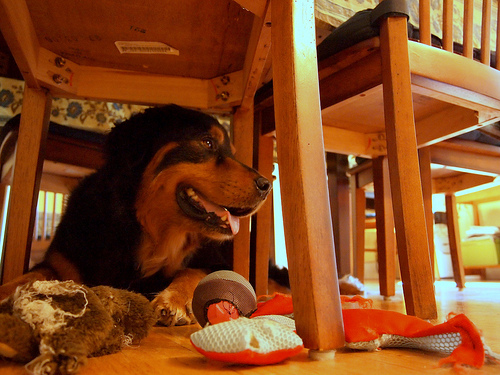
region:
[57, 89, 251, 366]
a dog is under the table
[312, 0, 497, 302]
wooden chair with cushion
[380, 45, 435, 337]
stand of the wooden chair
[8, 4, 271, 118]
wooden dining table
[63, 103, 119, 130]
white color flower designed dining table cloth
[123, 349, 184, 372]
brown color floor tiles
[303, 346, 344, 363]
rubber bush under the stand of the table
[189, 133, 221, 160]
eye of the dog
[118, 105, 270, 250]
head of the dog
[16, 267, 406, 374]
many things under the table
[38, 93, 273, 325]
a brown and black dog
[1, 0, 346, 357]
a dog sitting under a chair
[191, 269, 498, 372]
the toys of the dog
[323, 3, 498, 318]
the bottom of a wooden chair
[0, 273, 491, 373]
toys on the floor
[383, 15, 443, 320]
the wooden leg of the chair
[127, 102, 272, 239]
the face of the dog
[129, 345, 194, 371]
the hardwood floor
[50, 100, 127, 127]
the flower print of the table cloth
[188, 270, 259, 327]
a ball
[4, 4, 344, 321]
the dog is under the chair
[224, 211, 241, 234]
the red tongue of the dog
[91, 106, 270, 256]
the head of the rottweiler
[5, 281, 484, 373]
the dog is playing with these toys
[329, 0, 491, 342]
more chairs in the scene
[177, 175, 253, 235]
the open mouth of the dog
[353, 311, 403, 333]
this color is orange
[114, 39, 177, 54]
an attached label on the chair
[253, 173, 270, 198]
the nose of the dog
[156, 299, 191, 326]
rhe claws of the dog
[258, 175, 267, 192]
The nose of the dog.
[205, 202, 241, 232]
The tongue of the dog.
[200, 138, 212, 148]
The eye of the dog.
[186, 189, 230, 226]
The teeth of the dog.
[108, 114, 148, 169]
The ear of the dog.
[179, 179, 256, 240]
The mouth of the dog.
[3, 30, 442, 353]
The legs of the wooden chairs.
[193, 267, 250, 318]
The ball near the dog.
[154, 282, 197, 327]
The paw of the dog.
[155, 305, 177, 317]
The nails on the dog's paw.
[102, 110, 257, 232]
black and brown head of dog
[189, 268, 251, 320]
small ball toy by dog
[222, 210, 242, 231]
pink tongue of dog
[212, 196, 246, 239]
tongue of dog sticking out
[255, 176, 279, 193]
black snout of dog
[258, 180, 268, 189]
small black nostril of dog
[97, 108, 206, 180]
black fur on dog head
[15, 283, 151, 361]
chewed up stuff toy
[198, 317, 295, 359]
red and white dog toy